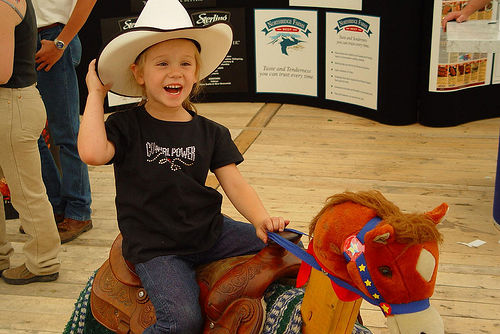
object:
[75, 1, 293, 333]
boy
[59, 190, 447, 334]
pony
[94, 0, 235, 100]
hat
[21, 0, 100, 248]
man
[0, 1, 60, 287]
woman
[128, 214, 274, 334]
jeans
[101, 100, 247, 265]
shirt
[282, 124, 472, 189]
floor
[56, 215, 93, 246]
shoe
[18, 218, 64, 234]
shoe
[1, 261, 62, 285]
shoe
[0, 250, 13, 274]
shoe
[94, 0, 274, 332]
cowboy outfit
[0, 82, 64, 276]
pants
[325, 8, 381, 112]
promotional sign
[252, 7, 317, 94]
promotional sign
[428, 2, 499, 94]
sign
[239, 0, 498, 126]
wall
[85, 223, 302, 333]
saddle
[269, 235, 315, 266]
reins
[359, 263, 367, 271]
star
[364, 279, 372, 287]
star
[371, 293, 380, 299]
star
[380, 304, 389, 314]
star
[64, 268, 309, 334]
blanket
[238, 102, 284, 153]
stripe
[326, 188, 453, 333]
head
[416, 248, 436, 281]
diamond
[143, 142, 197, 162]
cowgirl power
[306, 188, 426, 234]
mane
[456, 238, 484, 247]
garbage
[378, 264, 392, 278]
eye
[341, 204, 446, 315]
bridle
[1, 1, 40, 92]
shirt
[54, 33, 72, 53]
wrist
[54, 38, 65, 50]
wristwatch